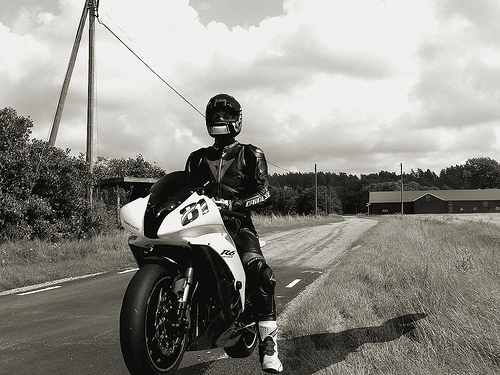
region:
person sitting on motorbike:
[126, 85, 298, 373]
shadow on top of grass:
[312, 300, 432, 372]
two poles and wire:
[53, 11, 127, 143]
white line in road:
[280, 267, 310, 297]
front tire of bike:
[110, 252, 184, 372]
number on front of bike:
[169, 190, 216, 237]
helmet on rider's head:
[196, 82, 248, 155]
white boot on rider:
[253, 314, 290, 373]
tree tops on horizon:
[316, 161, 461, 189]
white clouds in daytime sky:
[282, 32, 404, 118]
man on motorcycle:
[123, 87, 304, 367]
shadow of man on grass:
[218, 170, 416, 368]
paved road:
[8, 271, 212, 364]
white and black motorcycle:
[107, 165, 251, 365]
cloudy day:
[169, 29, 405, 109]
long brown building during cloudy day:
[335, 150, 498, 211]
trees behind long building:
[358, 158, 498, 223]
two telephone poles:
[21, 45, 121, 175]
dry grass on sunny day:
[357, 231, 463, 361]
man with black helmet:
[180, 87, 262, 194]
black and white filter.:
[3, 2, 492, 372]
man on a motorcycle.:
[114, 90, 288, 373]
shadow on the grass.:
[247, 300, 436, 369]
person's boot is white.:
[252, 312, 287, 374]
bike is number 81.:
[175, 196, 212, 227]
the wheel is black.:
[117, 257, 192, 374]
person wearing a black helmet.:
[195, 88, 247, 145]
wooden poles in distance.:
[34, 2, 104, 197]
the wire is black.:
[95, 14, 215, 125]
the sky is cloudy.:
[2, 0, 498, 162]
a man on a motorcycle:
[185, 91, 285, 369]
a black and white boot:
[255, 319, 285, 370]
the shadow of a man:
[174, 307, 418, 373]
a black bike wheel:
[119, 261, 187, 367]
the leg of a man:
[233, 227, 274, 324]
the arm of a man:
[225, 141, 268, 205]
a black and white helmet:
[205, 93, 242, 131]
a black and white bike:
[116, 161, 249, 368]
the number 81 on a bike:
[179, 195, 208, 226]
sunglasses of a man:
[209, 114, 231, 121]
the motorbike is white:
[93, 186, 308, 366]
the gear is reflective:
[187, 141, 287, 326]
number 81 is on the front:
[178, 189, 226, 235]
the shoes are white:
[256, 331, 295, 373]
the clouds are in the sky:
[296, 118, 458, 162]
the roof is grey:
[436, 187, 498, 204]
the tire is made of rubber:
[111, 284, 184, 371]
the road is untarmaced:
[288, 223, 353, 257]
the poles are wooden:
[310, 164, 410, 221]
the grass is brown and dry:
[353, 236, 421, 358]